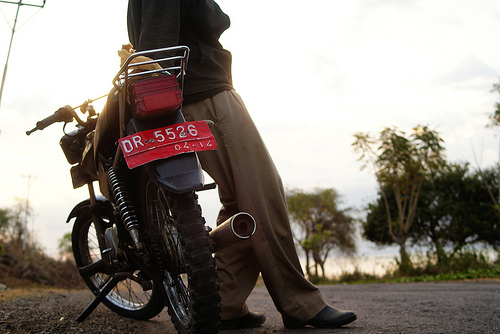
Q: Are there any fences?
A: No, there are no fences.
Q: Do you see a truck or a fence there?
A: No, there are no fences or trucks.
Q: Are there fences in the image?
A: No, there are no fences.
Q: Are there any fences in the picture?
A: No, there are no fences.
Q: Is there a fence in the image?
A: No, there are no fences.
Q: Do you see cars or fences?
A: No, there are no fences or cars.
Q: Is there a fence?
A: No, there are no fences.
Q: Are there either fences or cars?
A: No, there are no fences or cars.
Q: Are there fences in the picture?
A: No, there are no fences.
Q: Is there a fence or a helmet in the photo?
A: No, there are no fences or helmets.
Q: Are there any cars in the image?
A: No, there are no cars.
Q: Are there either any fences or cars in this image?
A: No, there are no cars or fences.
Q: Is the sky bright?
A: Yes, the sky is bright.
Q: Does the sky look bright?
A: Yes, the sky is bright.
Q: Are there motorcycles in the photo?
A: Yes, there is a motorcycle.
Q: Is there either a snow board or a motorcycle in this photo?
A: Yes, there is a motorcycle.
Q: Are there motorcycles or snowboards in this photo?
A: Yes, there is a motorcycle.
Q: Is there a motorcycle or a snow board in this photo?
A: Yes, there is a motorcycle.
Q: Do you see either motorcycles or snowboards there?
A: Yes, there is a motorcycle.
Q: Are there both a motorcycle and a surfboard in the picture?
A: No, there is a motorcycle but no surfboards.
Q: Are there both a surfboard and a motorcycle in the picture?
A: No, there is a motorcycle but no surfboards.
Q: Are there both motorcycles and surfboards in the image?
A: No, there is a motorcycle but no surfboards.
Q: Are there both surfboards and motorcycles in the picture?
A: No, there is a motorcycle but no surfboards.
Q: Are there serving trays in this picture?
A: No, there are no serving trays.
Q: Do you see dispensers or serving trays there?
A: No, there are no serving trays or dispensers.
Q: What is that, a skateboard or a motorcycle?
A: That is a motorcycle.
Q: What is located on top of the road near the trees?
A: The motorbike is on top of the road.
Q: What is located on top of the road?
A: The motorbike is on top of the road.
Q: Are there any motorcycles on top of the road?
A: Yes, there is a motorcycle on top of the road.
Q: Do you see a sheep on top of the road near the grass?
A: No, there is a motorcycle on top of the road.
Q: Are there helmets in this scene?
A: No, there are no helmets.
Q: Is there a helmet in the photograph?
A: No, there are no helmets.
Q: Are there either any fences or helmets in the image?
A: No, there are no helmets or fences.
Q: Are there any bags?
A: No, there are no bags.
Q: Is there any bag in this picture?
A: No, there are no bags.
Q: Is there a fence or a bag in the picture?
A: No, there are no bags or fences.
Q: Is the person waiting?
A: Yes, the person is waiting.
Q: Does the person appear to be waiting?
A: Yes, the person is waiting.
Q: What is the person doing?
A: The person is waiting.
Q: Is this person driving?
A: No, the person is waiting.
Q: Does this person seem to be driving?
A: No, the person is waiting.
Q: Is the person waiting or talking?
A: The person is waiting.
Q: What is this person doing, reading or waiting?
A: The person is waiting.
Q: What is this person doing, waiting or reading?
A: The person is waiting.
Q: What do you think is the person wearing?
A: The person is wearing trousers.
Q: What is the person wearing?
A: The person is wearing trousers.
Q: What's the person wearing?
A: The person is wearing trousers.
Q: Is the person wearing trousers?
A: Yes, the person is wearing trousers.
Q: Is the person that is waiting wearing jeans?
A: No, the person is wearing trousers.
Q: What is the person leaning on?
A: The person is leaning on the motorcycle.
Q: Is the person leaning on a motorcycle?
A: Yes, the person is leaning on a motorcycle.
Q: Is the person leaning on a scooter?
A: No, the person is leaning on a motorcycle.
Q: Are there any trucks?
A: No, there are no trucks.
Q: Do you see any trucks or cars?
A: No, there are no trucks or cars.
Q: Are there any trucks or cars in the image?
A: No, there are no trucks or cars.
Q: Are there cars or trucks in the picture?
A: No, there are no trucks or cars.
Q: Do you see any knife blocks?
A: No, there are no knife blocks.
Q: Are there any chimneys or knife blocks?
A: No, there are no knife blocks or chimneys.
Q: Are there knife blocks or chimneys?
A: No, there are no knife blocks or chimneys.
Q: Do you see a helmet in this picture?
A: No, there are no helmets.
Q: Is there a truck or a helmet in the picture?
A: No, there are no helmets or trucks.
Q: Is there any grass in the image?
A: Yes, there is grass.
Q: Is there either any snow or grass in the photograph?
A: Yes, there is grass.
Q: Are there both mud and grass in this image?
A: No, there is grass but no mud.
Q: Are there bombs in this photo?
A: No, there are no bombs.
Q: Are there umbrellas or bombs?
A: No, there are no bombs or umbrellas.